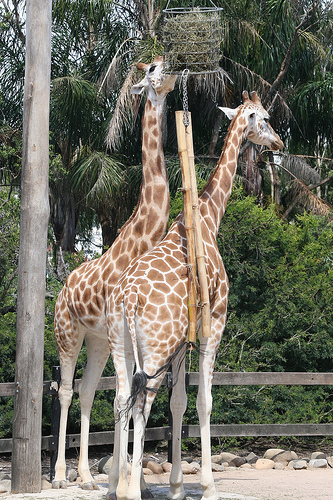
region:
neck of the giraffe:
[220, 159, 239, 181]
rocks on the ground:
[257, 454, 306, 468]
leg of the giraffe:
[194, 404, 220, 494]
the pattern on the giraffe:
[148, 261, 182, 307]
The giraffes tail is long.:
[120, 291, 150, 414]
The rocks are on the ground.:
[222, 445, 330, 471]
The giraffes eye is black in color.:
[260, 115, 268, 122]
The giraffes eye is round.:
[148, 65, 156, 72]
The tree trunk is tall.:
[8, 1, 56, 496]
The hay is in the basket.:
[159, 2, 223, 77]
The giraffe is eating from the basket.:
[130, 53, 180, 101]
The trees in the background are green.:
[236, 216, 304, 292]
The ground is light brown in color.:
[243, 474, 312, 499]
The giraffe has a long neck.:
[136, 97, 169, 218]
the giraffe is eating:
[127, 34, 220, 110]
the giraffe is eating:
[118, 30, 197, 122]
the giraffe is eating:
[120, 44, 179, 96]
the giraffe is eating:
[123, 40, 182, 104]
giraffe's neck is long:
[199, 119, 242, 233]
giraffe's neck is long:
[200, 122, 240, 225]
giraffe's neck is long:
[199, 108, 248, 220]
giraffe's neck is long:
[192, 112, 243, 252]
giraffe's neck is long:
[188, 107, 260, 264]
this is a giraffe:
[111, 52, 295, 496]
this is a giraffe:
[49, 52, 174, 493]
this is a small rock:
[244, 450, 276, 481]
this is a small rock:
[219, 439, 251, 481]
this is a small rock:
[307, 462, 326, 476]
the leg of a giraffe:
[43, 315, 82, 488]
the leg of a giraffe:
[99, 359, 140, 484]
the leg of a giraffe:
[105, 331, 182, 493]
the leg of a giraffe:
[185, 323, 265, 499]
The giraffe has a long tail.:
[119, 293, 152, 407]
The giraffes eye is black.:
[262, 115, 269, 124]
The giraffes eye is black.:
[149, 63, 157, 72]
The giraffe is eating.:
[131, 54, 184, 101]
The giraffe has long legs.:
[52, 354, 109, 491]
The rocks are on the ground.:
[225, 446, 325, 471]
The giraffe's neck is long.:
[132, 95, 171, 222]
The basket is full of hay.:
[159, 6, 226, 79]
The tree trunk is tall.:
[10, 0, 42, 492]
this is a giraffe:
[109, 83, 288, 497]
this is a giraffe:
[36, 46, 181, 493]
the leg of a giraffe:
[189, 287, 237, 497]